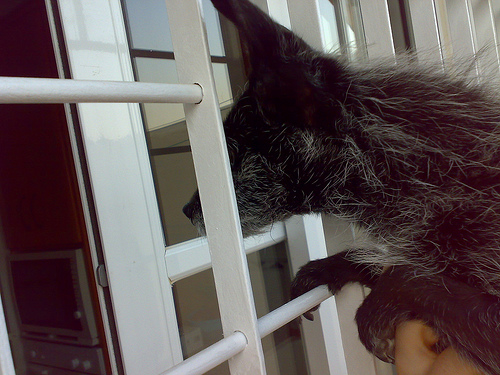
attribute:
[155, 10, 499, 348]
dog — black, gray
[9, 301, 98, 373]
knobs — white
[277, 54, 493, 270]
hair — long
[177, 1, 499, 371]
dog — black , gray , white, grey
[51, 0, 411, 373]
window — glass 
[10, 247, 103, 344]
television — large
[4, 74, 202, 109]
bar — white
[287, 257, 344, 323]
paw — black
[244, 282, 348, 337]
bar — white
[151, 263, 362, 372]
rail — white 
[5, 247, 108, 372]
oven — built-in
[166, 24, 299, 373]
board — white 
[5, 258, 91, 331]
screen — square 